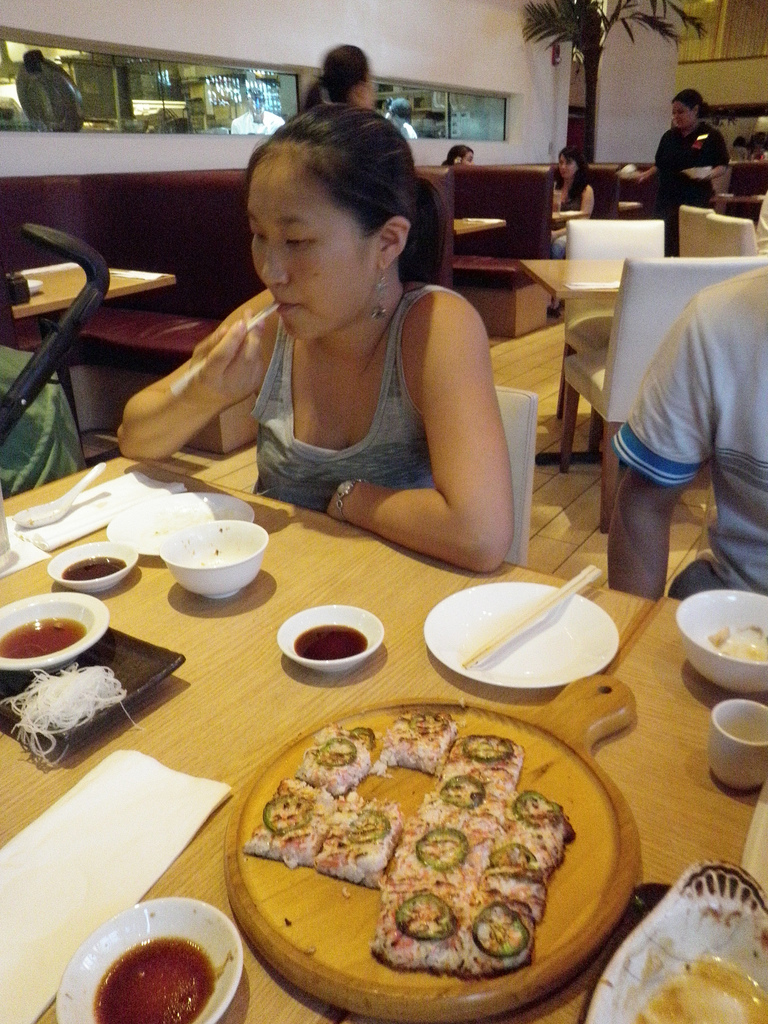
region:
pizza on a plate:
[505, 785, 578, 876]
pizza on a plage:
[453, 736, 527, 805]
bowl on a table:
[251, 571, 388, 697]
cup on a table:
[672, 676, 763, 776]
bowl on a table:
[53, 539, 137, 597]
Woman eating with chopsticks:
[101, 100, 545, 575]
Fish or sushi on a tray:
[250, 704, 574, 982]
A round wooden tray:
[216, 695, 659, 1020]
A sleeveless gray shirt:
[249, 330, 428, 502]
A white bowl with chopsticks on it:
[407, 570, 634, 700]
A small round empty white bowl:
[155, 513, 266, 596]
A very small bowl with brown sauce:
[275, 591, 389, 680]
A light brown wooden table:
[35, 442, 434, 728]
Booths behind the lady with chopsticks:
[21, 84, 702, 464]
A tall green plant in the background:
[515, 4, 655, 176]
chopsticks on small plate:
[459, 565, 608, 676]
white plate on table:
[422, 570, 626, 696]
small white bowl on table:
[259, 591, 401, 678]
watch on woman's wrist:
[324, 473, 364, 519]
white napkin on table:
[2, 746, 236, 1021]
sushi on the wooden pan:
[292, 723, 373, 801]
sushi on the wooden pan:
[321, 790, 398, 886]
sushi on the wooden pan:
[371, 874, 468, 985]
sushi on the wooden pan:
[438, 728, 524, 793]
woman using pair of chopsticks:
[114, 91, 515, 571]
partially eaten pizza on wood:
[218, 670, 646, 1022]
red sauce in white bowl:
[51, 885, 246, 1022]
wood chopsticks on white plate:
[422, 556, 622, 689]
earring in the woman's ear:
[368, 260, 392, 326]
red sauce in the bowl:
[93, 942, 193, 1012]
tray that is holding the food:
[550, 744, 603, 795]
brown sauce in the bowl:
[281, 620, 378, 677]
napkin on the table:
[100, 764, 152, 833]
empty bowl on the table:
[174, 539, 271, 598]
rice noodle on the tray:
[48, 680, 95, 706]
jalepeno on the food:
[401, 891, 454, 942]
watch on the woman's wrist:
[333, 482, 368, 497]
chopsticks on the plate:
[511, 593, 561, 647]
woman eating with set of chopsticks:
[115, 99, 517, 574]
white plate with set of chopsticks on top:
[418, 572, 618, 692]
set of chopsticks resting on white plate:
[457, 556, 600, 670]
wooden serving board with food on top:
[219, 666, 643, 1022]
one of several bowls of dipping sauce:
[272, 602, 390, 675]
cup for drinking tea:
[691, 697, 766, 795]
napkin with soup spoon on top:
[7, 461, 185, 552]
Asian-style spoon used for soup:
[7, 456, 124, 530]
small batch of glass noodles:
[8, 659, 144, 772]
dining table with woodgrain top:
[0, 451, 766, 1022]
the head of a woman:
[218, 156, 470, 335]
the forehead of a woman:
[243, 159, 313, 205]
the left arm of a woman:
[359, 370, 512, 574]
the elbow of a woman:
[441, 504, 516, 587]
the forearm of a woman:
[345, 478, 452, 553]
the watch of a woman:
[320, 484, 378, 516]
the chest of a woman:
[271, 373, 385, 458]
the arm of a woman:
[103, 363, 273, 465]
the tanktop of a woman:
[261, 356, 424, 504]